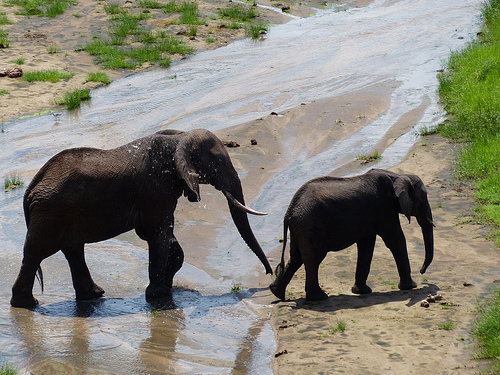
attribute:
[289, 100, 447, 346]
elephant — large, grey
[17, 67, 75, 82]
grass — patch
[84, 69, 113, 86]
grass — patch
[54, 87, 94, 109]
grass — patch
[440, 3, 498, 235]
grass — patch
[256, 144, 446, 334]
elephant — grey, large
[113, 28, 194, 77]
grass — patch